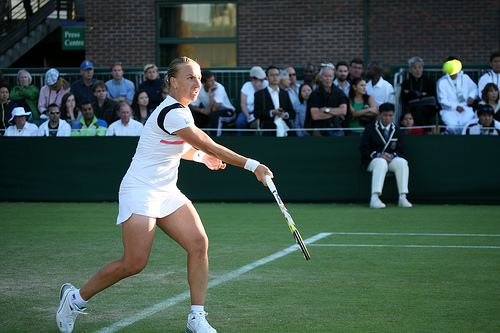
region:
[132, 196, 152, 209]
woman wearing white skirt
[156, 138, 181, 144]
red stripe on shirt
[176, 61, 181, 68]
woman has blonde hair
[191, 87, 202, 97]
womans mouth is open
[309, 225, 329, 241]
white line on court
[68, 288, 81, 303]
woman wearing white socks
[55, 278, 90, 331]
woman wearing white sneakers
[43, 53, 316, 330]
woman playing tennis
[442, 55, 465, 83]
tennis ball in the air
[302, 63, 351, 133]
man standing with arms folded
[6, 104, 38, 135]
person in a white hat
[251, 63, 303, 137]
person watching the tennis match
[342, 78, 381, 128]
woman wearing a green shirt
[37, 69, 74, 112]
person wearing a pink shirt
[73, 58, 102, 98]
man wearing a blue hat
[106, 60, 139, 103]
man wearing a button down shirt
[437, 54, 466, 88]
tennis ball in flight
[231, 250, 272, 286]
white line on tennis court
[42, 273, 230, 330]
woman wearing white tennis shoes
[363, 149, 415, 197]
person wearing white pants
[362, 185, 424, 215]
person wearing white shoes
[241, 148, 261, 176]
player wearing white wrist band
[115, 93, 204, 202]
player wearing white tennis shirt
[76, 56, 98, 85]
man wearing blue hat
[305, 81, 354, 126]
man in black shirt with his arms crossed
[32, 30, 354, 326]
this is a woman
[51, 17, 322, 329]
she is a tennis player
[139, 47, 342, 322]
she is holding a racket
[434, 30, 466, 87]
this is a tennis ball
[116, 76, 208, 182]
woman wearing a white shirt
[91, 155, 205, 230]
woman wearing a white skirt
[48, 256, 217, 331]
woman wearing white tennis shoes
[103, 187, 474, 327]
white lines on court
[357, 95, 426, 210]
man sitting on the side of the court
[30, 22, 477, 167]
spectators watching tennis match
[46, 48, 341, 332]
A young woman playing tennis.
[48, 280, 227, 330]
A pair of white tennis shoes.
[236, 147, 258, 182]
White wristband on right wrist.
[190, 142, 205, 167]
White wristband on left wrist.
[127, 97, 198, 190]
A white short sleeve shirt.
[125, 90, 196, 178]
White shirt with black and red stripes.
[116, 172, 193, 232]
A white tennis skirt.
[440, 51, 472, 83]
A yellow tennis ball in the air.